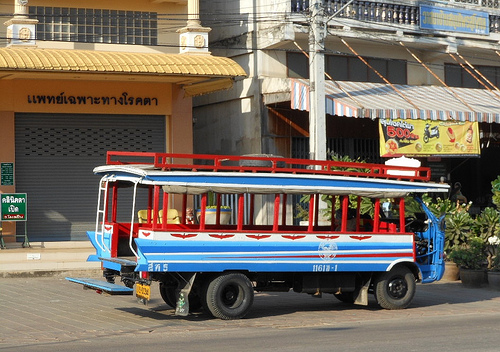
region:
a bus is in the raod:
[62, 115, 449, 315]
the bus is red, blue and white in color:
[86, 146, 446, 313]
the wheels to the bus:
[130, 261, 417, 319]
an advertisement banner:
[376, 109, 483, 166]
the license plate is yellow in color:
[125, 281, 156, 300]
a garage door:
[15, 111, 175, 251]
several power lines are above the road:
[16, 0, 491, 88]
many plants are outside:
[333, 151, 499, 291]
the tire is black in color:
[198, 275, 261, 321]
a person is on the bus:
[330, 181, 379, 236]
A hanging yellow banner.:
[377, 119, 482, 156]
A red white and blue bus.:
[64, 147, 450, 319]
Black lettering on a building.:
[25, 87, 159, 110]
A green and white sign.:
[0, 190, 28, 223]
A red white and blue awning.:
[291, 75, 499, 125]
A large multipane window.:
[28, 3, 160, 46]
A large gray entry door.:
[14, 109, 168, 242]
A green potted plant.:
[447, 241, 488, 289]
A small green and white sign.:
[0, 159, 15, 186]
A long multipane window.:
[286, 48, 408, 87]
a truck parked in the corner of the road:
[88, 141, 450, 317]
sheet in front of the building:
[308, 68, 498, 113]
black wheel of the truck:
[372, 270, 424, 306]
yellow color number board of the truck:
[130, 278, 154, 305]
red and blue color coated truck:
[116, 154, 415, 266]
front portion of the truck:
[412, 173, 457, 300]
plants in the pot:
[441, 205, 495, 291]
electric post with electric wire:
[294, 8, 348, 203]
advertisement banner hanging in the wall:
[380, 118, 485, 157]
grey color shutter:
[25, 115, 99, 234]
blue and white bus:
[74, 145, 392, 299]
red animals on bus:
[161, 208, 381, 256]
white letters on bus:
[130, 240, 347, 270]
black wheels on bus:
[191, 250, 418, 314]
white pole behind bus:
[294, 41, 349, 186]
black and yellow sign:
[8, 74, 186, 131]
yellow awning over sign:
[10, 47, 227, 117]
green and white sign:
[2, 188, 36, 232]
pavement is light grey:
[32, 257, 156, 342]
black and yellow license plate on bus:
[118, 275, 175, 316]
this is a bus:
[89, 144, 454, 337]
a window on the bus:
[159, 185, 207, 234]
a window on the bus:
[204, 186, 244, 233]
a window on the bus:
[243, 193, 280, 240]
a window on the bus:
[275, 186, 316, 235]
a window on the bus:
[312, 187, 344, 233]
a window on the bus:
[342, 188, 376, 241]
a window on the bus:
[374, 191, 402, 237]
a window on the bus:
[112, 185, 159, 229]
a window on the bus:
[204, 189, 219, 220]